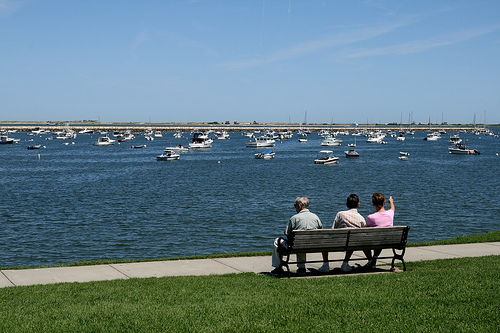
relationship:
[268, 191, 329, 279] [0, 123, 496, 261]
man in front ocean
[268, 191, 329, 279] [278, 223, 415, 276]
man sit on bench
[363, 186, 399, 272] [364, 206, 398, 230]
woman wears pink top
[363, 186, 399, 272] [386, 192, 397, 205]
woman pointing with hand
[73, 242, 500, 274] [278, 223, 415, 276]
sidewalk front a bench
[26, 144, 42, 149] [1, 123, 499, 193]
boat in ocean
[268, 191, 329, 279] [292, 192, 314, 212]
man has gray hair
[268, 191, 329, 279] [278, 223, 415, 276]
man sitting on bench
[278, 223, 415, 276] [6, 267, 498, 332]
bench near grass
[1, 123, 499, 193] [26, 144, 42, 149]
water crowded with boat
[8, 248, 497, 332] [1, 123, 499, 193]
shore of ocean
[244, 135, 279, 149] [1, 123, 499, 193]
boat floating on water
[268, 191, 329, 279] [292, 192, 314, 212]
man with gray hair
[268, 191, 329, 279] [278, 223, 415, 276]
man on a bench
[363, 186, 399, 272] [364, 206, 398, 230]
woman with pink shirt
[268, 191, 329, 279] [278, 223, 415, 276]
man on bench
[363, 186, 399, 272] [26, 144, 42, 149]
woman pointing boat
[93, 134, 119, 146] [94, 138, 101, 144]
boat has motor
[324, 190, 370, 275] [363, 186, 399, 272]
man with a woman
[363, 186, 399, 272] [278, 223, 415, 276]
woman sitting on bench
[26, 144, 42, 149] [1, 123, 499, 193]
boat on river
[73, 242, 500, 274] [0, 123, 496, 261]
sidewalk beside ocean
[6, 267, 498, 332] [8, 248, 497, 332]
green grass covering ground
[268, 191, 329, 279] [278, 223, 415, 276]
man seated on bench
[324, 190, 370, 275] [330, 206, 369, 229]
young man wearing plaid shirt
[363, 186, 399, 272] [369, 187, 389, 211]
woman has short  hair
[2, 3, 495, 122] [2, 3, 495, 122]
clouds in sky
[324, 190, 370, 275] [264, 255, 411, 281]
person wearing shoes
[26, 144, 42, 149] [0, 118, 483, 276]
boat in harbor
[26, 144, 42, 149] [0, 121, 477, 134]
boat in harbor